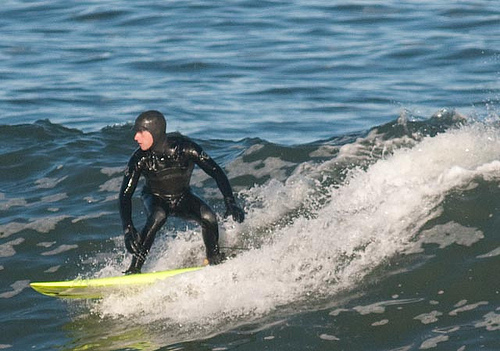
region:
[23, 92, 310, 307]
a man is surfing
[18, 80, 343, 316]
a man catching a wave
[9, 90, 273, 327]
a man riding a wave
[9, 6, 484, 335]
a man surfs the ocean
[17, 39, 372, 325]
a man hanging ten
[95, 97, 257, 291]
man in a wetsuit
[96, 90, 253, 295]
a tight black wetsuit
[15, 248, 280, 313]
a bright yellow surfboard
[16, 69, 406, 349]
a man rides an ocean wave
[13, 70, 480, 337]
a man balances on a wave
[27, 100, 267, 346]
a black sufer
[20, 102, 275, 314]
a person surfs on water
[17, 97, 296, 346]
a man in black attire on a surfboard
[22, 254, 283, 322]
a yellow surfboard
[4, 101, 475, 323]
a huge wave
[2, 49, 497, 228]
blue water in the background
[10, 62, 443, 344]
a scene outdoors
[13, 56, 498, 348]
a scene during the day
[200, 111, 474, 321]
a splash of foam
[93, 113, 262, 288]
a person looking left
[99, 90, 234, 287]
A person in a wet suit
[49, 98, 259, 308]
A person on a surf board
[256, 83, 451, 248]
A wave crashing in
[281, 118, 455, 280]
Water bubbling and crashing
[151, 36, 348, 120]
A large body of water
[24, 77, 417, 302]
A man surfing in ocean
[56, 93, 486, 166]
A wave with a man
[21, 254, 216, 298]
A yellow surf board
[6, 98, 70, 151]
A small wave crest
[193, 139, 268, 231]
The left arm of a man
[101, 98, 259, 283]
a surfer in a black wetsuit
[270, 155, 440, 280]
white foam on top of waves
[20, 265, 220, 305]
a light green surfboard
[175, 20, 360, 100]
ocean water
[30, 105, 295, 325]
a man on a green surfboard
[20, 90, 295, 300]
a man surfing a wave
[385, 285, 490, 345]
water with foam on top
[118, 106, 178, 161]
a man with black hair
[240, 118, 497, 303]
a wave on top of the water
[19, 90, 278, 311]
a surfer balancing on a surfboard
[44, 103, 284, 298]
woman is surfing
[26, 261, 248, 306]
the surfboard is yellow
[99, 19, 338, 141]
the water is green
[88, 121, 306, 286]
woman is wearing a wetsuit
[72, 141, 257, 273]
the wet suit is black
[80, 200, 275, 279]
woman wearing gloves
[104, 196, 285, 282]
the gloves are black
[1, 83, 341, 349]
woman riding the waves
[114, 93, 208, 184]
the hood is black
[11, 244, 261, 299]
surfboard on the water